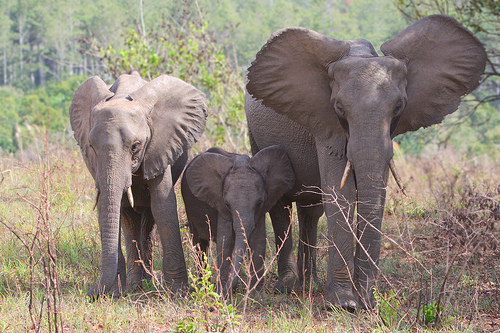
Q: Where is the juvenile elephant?
A: In the middle.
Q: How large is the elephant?
A: Very huge.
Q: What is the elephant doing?
A: Standing in the wild.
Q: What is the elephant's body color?
A: Gray.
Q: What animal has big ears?
A: The elephant.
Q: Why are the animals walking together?
A: Are an elephants family.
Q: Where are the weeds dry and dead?
A: In the wild.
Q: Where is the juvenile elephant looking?
A: At the ground.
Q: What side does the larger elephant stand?
A: Right side.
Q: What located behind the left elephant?
A: Trees.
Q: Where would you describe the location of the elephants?
A: A field.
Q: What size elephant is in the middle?
A: A baby elephant.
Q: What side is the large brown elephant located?
A: Right side.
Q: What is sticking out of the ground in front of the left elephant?
A: Sticks.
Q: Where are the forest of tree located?
A: Behind the elephants.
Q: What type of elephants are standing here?
A: Mommy, and 2 babies.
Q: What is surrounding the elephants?
A: Green brush everywhere.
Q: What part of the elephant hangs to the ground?
A: The trunk.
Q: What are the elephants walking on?
A: Dry grass.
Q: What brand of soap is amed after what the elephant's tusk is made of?
A: Ivory.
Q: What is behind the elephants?
A: Trees.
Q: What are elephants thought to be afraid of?
A: Mice.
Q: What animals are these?
A: Elephants.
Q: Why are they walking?
A: To move.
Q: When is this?
A: Daytime.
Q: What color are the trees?
A: Green.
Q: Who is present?
A: Nobody.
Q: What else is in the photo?
A: Plants.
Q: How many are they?
A: Three.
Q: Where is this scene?
A: In Africa.